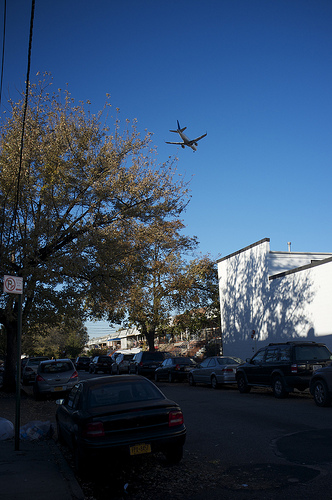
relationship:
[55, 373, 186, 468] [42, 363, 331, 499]
car on street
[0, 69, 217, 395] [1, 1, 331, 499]
tree in city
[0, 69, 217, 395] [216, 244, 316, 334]
tree has a shadow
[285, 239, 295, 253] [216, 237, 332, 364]
smokestack on building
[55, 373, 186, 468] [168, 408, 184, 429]
car has a tail light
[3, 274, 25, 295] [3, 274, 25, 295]
sign says sign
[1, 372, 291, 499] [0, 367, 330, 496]
leaves on ground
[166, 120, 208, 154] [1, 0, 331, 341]
airplane in sky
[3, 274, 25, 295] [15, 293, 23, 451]
sign on a pole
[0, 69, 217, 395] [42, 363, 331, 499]
tree next to street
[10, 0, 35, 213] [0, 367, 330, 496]
wire above ground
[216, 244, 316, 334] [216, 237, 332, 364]
shadow on building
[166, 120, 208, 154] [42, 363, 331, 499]
airplane above street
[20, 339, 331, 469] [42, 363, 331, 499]
cars parked on street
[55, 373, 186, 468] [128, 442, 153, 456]
car has a license plate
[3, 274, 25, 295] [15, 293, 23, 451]
sign on pole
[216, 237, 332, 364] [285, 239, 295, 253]
building has a smokestack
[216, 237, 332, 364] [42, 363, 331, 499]
building near street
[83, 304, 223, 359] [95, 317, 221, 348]
building has windows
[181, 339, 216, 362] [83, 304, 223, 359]
steps to building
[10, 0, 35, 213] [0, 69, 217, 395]
wire near tree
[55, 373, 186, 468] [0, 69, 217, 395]
car near tree